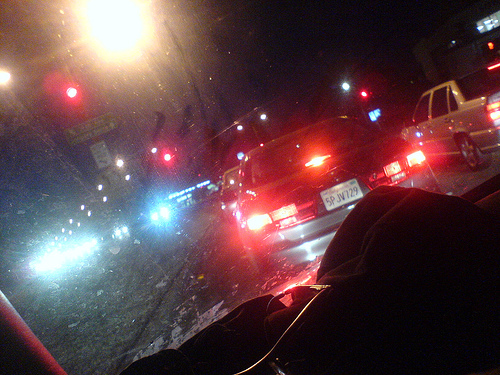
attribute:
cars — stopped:
[0, 57, 500, 374]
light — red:
[66, 86, 79, 98]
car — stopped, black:
[234, 113, 442, 276]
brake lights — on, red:
[247, 149, 428, 231]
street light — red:
[359, 91, 369, 99]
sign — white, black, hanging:
[89, 140, 114, 170]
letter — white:
[64, 115, 113, 147]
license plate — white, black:
[319, 177, 364, 210]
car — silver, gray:
[400, 57, 500, 172]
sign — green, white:
[63, 111, 120, 148]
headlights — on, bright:
[26, 198, 173, 285]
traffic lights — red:
[66, 90, 370, 163]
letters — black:
[325, 186, 360, 207]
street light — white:
[1, 0, 175, 112]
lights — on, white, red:
[1, 0, 500, 282]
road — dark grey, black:
[1, 148, 500, 374]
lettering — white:
[65, 111, 118, 147]